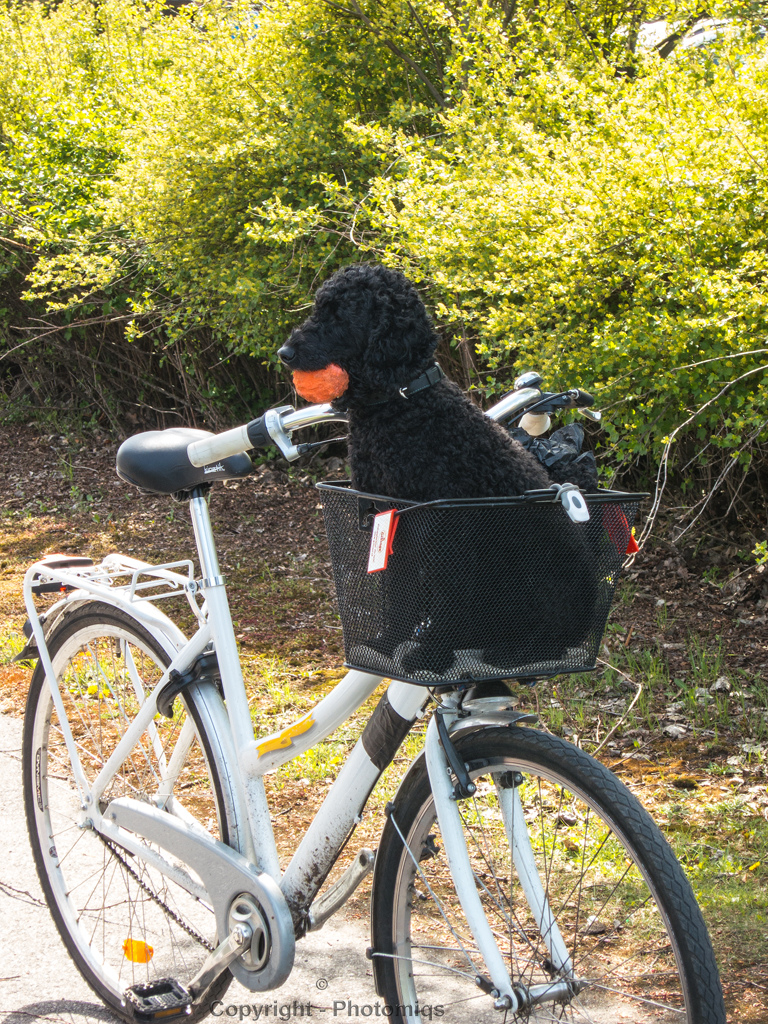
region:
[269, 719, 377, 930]
near the peddlals its maddy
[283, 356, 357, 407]
orange ball in dogs mouth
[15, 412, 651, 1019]
A white bicycle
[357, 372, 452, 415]
A black dog collar with silver buckle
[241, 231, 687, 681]
A black dog sitting in a basket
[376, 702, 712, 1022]
black bicycle tire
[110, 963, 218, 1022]
A black bicycle pedal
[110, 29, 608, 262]
green folliage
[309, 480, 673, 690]
A black bicycle basket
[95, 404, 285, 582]
silver and black bicycle seat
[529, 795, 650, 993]
The spokes on a bicycle wheel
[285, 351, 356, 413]
orange ball in a dog's mouth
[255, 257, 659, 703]
black dog in a bike basket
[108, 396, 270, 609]
raised seat on a bike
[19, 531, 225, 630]
storage rack over rear fender of bike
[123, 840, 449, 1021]
pedals on a bicycle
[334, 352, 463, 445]
black collar on a black dog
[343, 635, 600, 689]
blanket or towel in the bottom of the basket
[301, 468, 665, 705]
black mesh bicycle basket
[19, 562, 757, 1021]
white metal frame bike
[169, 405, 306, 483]
white grip on bicycle handlebar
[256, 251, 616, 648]
cute black dog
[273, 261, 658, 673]
Cute black dog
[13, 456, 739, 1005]
Bicycle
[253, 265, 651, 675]
Cute dog in a basket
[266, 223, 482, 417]
dog with a ball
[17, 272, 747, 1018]
Dog with a ball in a basket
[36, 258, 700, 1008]
Dog with a ball in a bicycle basket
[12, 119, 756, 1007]
Dog with a ball in a bicycle basket, infront of a big bush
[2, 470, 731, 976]
Bicycle with a basket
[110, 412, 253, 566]
bicycle seat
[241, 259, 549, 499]
A BLUE COLOR DOLL IN THECYCLE BOX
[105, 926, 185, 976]
A YELLOW REFLECTOR IN BACK WHEEL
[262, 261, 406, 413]
PINK COLOR BALL IN THE MOUTH OF DOLL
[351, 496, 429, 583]
ADDRESS TAG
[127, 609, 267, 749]
THE BICYCLE IS NOT LOCKED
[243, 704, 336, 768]
A YELLOW STICKER PASTED ON FRAME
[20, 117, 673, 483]
BEAUTIFUL BACKGROUND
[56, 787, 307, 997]
CYCLE CHAIN IS NOT FULLY COVERED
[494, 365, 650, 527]
SOME OTHER THINGS ARE IN THE BASKET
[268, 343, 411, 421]
a dog holding an orange ball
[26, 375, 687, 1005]
the bike is white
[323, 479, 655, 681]
the bike has a black basket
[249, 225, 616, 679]
there is a black furry dog in basket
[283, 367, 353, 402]
the dog is holding a orange ball in mouth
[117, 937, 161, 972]
orange reflector lights are on the bike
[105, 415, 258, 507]
there is a black seat on the bikw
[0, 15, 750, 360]
green bushes are behind the bike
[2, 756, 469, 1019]
bike is on the pavement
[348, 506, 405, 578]
the basket has red tags on it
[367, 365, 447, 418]
dog is wearing a black collar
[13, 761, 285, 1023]
Sidewalk shows evidence of sunlight and shadow.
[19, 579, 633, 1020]
White bike shows yellow light and detail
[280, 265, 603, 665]
Black poodle in black basket.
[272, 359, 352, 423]
Orange ball in pooch's mouth.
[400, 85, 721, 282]
Bright green shrubbery.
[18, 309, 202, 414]
Brown stalks and undergrowth.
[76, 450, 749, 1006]
Ground shows patchy grass, rocks and dirt.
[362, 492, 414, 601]
Red and white tag folded over wire basket.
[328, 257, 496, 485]
Dog shows curly hair and floppy ears.